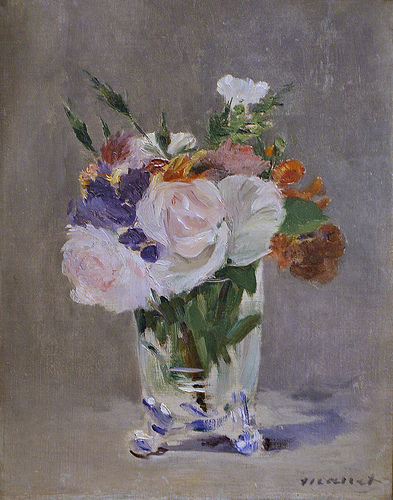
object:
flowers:
[130, 130, 197, 163]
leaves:
[64, 106, 93, 151]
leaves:
[83, 69, 129, 116]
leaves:
[155, 108, 171, 153]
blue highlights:
[236, 433, 253, 452]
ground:
[72, 454, 192, 494]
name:
[300, 473, 385, 486]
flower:
[217, 74, 272, 118]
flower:
[268, 223, 348, 286]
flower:
[203, 138, 272, 176]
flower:
[59, 222, 151, 313]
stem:
[177, 321, 208, 414]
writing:
[301, 473, 375, 486]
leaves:
[194, 299, 242, 348]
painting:
[1, 0, 392, 496]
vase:
[128, 259, 264, 457]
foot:
[127, 413, 170, 456]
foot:
[231, 422, 263, 455]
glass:
[128, 257, 263, 455]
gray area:
[0, 1, 67, 94]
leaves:
[156, 318, 167, 346]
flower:
[135, 174, 286, 295]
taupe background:
[0, 0, 393, 56]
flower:
[67, 159, 150, 235]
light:
[170, 367, 206, 394]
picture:
[0, 0, 393, 500]